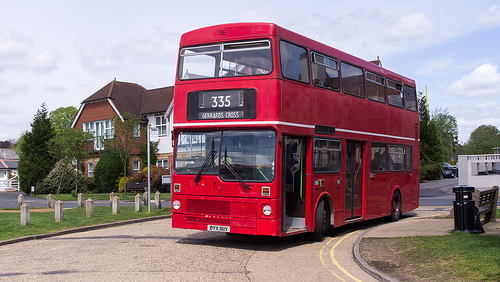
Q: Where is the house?
A: Behind the bus.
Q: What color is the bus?
A: Red.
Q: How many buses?
A: 1.